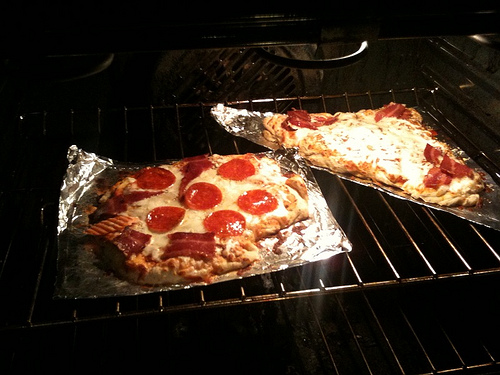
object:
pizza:
[56, 145, 315, 289]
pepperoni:
[182, 179, 222, 210]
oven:
[0, 0, 500, 374]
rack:
[1, 84, 500, 334]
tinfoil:
[45, 144, 352, 301]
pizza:
[261, 97, 489, 211]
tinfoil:
[205, 97, 498, 235]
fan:
[146, 35, 325, 144]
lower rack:
[145, 120, 498, 374]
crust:
[79, 146, 312, 286]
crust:
[259, 100, 487, 210]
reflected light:
[59, 146, 352, 270]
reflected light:
[206, 97, 274, 138]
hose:
[49, 54, 117, 91]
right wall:
[0, 55, 113, 373]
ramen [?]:
[323, 117, 430, 159]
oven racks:
[1, 84, 499, 375]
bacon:
[159, 225, 218, 262]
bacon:
[415, 142, 476, 188]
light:
[244, 33, 372, 69]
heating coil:
[247, 40, 374, 75]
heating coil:
[31, 53, 124, 91]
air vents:
[177, 49, 294, 111]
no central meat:
[307, 124, 429, 186]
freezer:
[262, 4, 267, 8]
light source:
[468, 33, 476, 40]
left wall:
[415, 20, 499, 374]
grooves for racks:
[423, 35, 499, 179]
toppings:
[81, 153, 285, 262]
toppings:
[262, 98, 492, 207]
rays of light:
[272, 150, 356, 344]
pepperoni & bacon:
[73, 152, 275, 264]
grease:
[176, 208, 206, 232]